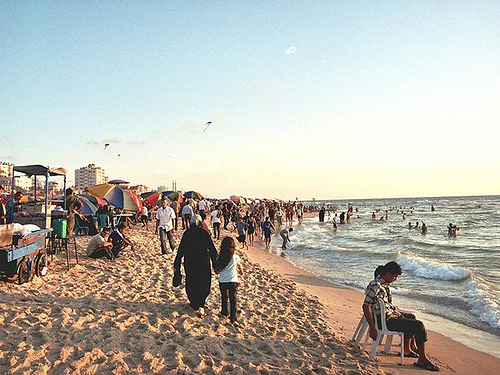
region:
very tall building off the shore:
[74, 165, 106, 192]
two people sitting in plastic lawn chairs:
[354, 260, 444, 370]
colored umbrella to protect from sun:
[89, 178, 148, 211]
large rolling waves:
[397, 252, 498, 327]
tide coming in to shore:
[390, 248, 498, 330]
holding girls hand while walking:
[173, 213, 245, 321]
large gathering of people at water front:
[157, 196, 312, 251]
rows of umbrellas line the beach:
[81, 186, 276, 212]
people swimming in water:
[334, 203, 462, 237]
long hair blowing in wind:
[215, 235, 237, 272]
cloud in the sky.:
[272, 37, 299, 69]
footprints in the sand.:
[89, 323, 110, 339]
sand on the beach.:
[452, 352, 476, 367]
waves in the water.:
[422, 255, 459, 279]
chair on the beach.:
[375, 307, 393, 347]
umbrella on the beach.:
[100, 187, 137, 206]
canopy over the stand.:
[23, 163, 73, 180]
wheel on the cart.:
[16, 258, 37, 283]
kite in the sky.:
[91, 136, 113, 159]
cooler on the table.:
[50, 217, 69, 241]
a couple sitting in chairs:
[353, 261, 429, 366]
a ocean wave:
[426, 247, 493, 331]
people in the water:
[319, 196, 466, 245]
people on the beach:
[139, 196, 281, 321]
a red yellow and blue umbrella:
[86, 183, 143, 218]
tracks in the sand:
[44, 274, 150, 359]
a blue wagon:
[5, 222, 47, 281]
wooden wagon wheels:
[16, 254, 57, 281]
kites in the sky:
[97, 116, 225, 153]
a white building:
[73, 165, 105, 189]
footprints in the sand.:
[95, 322, 127, 339]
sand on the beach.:
[450, 343, 465, 359]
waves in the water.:
[402, 250, 454, 280]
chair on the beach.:
[379, 299, 386, 346]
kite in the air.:
[195, 120, 218, 137]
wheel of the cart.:
[16, 259, 32, 294]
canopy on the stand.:
[13, 163, 72, 175]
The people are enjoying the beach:
[0, 120, 491, 361]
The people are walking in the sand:
[15, 57, 481, 362]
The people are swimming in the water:
[21, 45, 488, 360]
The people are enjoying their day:
[17, 47, 482, 357]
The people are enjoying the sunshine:
[31, 50, 469, 353]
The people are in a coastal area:
[5, 45, 483, 350]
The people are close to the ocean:
[20, 38, 483, 348]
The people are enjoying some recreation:
[0, 36, 496, 362]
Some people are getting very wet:
[0, 35, 491, 356]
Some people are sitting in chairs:
[347, 250, 449, 374]